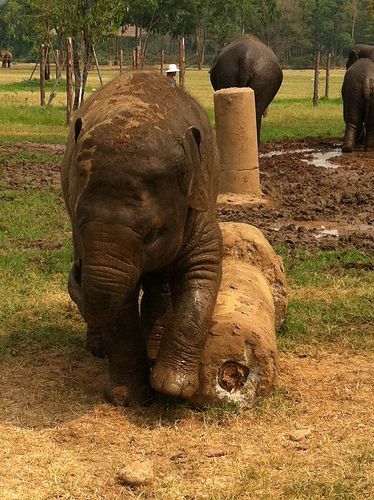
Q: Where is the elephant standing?
A: A grassy area.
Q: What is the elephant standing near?
A: A brown object.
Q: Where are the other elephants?
A: Behind the main elephant.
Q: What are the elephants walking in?
A: Grass.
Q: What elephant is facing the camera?
A: Elephant in front.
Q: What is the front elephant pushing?
A: Overturned stone pillar.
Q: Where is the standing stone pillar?
A: In the mud.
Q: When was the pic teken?
A: During the day.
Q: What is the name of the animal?
A: Elephant.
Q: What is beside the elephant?
A: Rock.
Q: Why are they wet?
A: They have entered in mud.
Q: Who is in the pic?
A: No one.